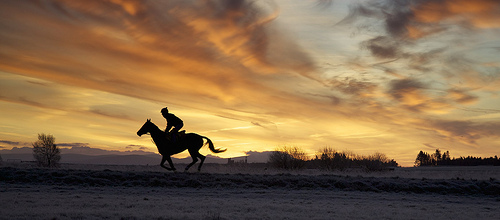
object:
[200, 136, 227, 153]
tail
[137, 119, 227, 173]
horse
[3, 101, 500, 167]
sunset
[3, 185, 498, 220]
sand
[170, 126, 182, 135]
legs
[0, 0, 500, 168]
orange sky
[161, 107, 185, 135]
man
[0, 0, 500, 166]
cloud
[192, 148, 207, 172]
back legs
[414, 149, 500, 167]
tree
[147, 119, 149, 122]
ears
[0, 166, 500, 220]
dirt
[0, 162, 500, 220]
ground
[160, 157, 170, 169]
leg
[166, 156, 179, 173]
leg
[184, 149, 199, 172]
leg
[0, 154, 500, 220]
field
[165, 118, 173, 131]
arms